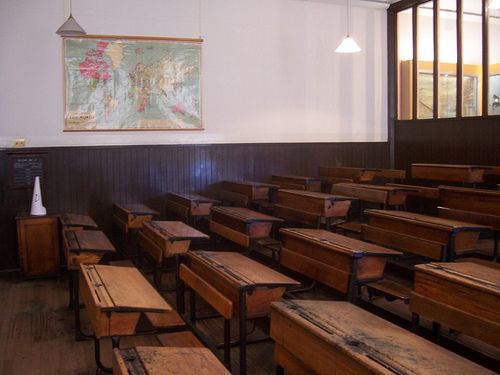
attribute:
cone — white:
[27, 166, 55, 216]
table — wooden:
[10, 214, 56, 283]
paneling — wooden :
[3, 143, 393, 268]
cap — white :
[26, 174, 45, 216]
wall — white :
[2, 0, 391, 148]